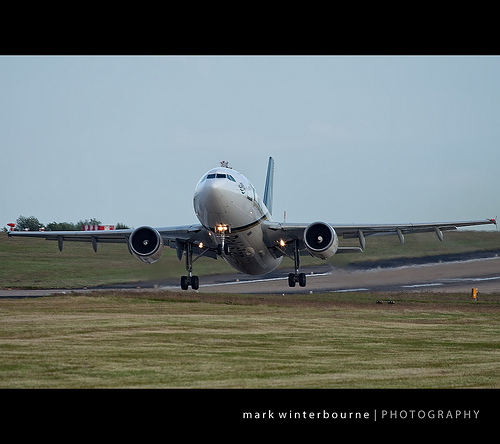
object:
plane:
[6, 155, 497, 292]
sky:
[0, 55, 499, 231]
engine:
[302, 219, 338, 261]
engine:
[125, 225, 163, 267]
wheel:
[286, 272, 297, 288]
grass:
[0, 287, 498, 390]